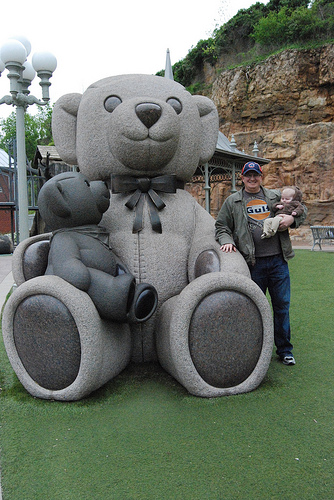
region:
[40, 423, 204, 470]
well manicured green grass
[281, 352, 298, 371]
silver sneakers on man's feet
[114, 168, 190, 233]
black shiny bow around man's neck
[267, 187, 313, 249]
baby in man's arm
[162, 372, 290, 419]
large dent in the gras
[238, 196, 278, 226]
blue words on orange sign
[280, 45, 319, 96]
black spot on rock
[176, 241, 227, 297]
spot on the gray bear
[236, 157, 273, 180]
blue and orange cap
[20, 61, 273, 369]
giant gray teddy bear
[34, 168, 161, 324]
Grey and black teddy bear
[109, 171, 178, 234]
Big black bow tie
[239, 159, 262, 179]
Blue and red cap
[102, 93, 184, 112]
Round black eyes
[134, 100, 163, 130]
Triangle shapped teddy bear nose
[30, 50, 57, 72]
Round white light bulb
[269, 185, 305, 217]
Small brown jacket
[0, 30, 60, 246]
Long tall light post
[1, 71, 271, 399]
Giant grey teddy bear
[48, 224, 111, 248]
large grey neck bandana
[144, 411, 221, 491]
the ground is green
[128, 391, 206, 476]
the ground is green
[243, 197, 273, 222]
Orange, blue and white Gulf Logo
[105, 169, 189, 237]
Large bow tie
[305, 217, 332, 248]
Park bench on right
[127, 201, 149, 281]
Center stitching on Papa Bear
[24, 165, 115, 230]
Upturned head of Baby Bear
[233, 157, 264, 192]
Smiling face of Dad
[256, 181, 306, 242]
Baby in Dad's arms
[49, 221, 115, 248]
Neckerchief on Baby Bear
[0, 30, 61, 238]
Many lanterned light post on left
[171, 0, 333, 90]
Vegetation on top of mountain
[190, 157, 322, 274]
The man holds a baby.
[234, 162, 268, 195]
The man is smiling.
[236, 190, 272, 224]
The man wears a Gulf shirt.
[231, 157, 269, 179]
The man wears a baseball cap.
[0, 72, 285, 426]
The teddy bear is enormous.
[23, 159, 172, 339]
A smaller teddy bear is in the larger one's lap.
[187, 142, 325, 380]
The man stands next to the teddy bear.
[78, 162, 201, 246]
The teddy bear wears a bow tie.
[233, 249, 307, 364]
The man wears jeans.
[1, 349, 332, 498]
The ground is green.